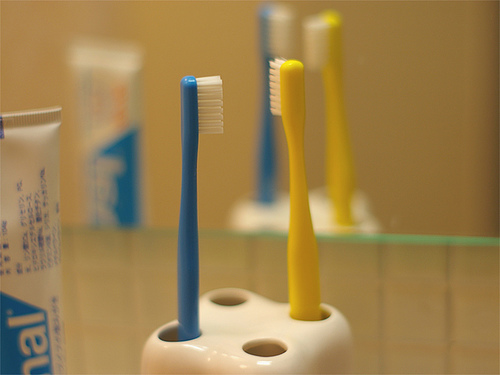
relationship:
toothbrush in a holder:
[177, 74, 224, 340] [140, 286, 353, 374]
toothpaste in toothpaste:
[1, 107, 68, 374] [0, 106, 68, 374]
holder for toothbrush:
[140, 286, 353, 374] [177, 74, 224, 340]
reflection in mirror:
[69, 2, 380, 240] [1, 1, 500, 249]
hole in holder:
[244, 339, 287, 358] [140, 286, 353, 374]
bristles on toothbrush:
[194, 76, 223, 136] [177, 74, 224, 340]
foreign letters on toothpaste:
[0, 166, 65, 372] [0, 106, 68, 374]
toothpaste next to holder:
[0, 106, 68, 374] [140, 286, 353, 374]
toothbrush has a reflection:
[177, 74, 224, 340] [69, 2, 380, 240]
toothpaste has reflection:
[0, 106, 68, 374] [69, 2, 380, 240]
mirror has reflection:
[1, 1, 500, 249] [69, 2, 380, 240]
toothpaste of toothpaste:
[0, 106, 68, 374] [1, 107, 68, 374]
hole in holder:
[209, 292, 249, 307] [140, 286, 353, 374]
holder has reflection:
[140, 286, 353, 374] [69, 2, 380, 240]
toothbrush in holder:
[177, 74, 224, 340] [140, 286, 353, 374]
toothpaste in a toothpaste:
[1, 107, 68, 374] [0, 106, 68, 374]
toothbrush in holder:
[268, 55, 323, 321] [140, 286, 353, 374]